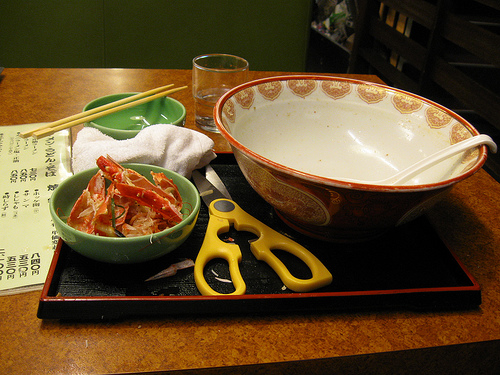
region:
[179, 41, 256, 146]
Small clear glass with water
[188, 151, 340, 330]
Scissors with yellow handles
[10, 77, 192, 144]
Two brown chopsticks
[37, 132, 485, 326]
Black and red food tray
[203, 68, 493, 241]
Large red white and brown bowl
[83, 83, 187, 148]
Small green bowl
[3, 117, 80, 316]
Black and white chinese menu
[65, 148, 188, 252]
Red crab meat in bowl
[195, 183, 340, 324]
Yellow handle on shears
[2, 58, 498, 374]
Pretty brown table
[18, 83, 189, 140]
Two chopsticks laying across a green bowl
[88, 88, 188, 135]
Small green bowl with chopsticks laying on top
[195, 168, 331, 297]
Pair of scissors with a yellow handle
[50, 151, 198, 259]
Medium green bowl with crustacean remains inside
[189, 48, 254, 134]
Small glass half-filled with water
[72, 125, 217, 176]
Small wadded up white towel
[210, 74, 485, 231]
Large empty bowl with decorative trim on the brim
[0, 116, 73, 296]
A light green laminated menu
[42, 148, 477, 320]
A black tray with a red brim full of dinner contents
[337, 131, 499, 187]
A white plastic spoon sitting in a large bowl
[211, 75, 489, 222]
ceramic Asian style soup bowl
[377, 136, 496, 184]
ceramic soup spoon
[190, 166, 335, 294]
kitchen scissors with yellow handles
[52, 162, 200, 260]
empty shrimp shells in green ceramic bowl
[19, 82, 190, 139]
pair of wooden chopsticks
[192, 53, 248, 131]
clear water glass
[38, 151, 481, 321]
laquered serving tray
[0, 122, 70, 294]
ethnic restaurant menu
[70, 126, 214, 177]
white cloth napkin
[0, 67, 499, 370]
three bowls, a menu and a glass on tabletopo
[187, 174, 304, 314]
yellow scissors on tray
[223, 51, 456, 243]
white bowl on black tray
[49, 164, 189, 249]
small green bowl on tray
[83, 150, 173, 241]
pieces of meat in green bowl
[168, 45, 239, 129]
glass of water on table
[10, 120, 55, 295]
white menu on left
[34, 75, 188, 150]
chop sticks on top of bowl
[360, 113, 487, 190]
white spoon in bowl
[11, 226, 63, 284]
black writing on white menu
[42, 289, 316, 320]
red edge of black tray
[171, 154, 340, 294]
yellow pair of scissors on a plate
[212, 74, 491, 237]
an empty bowl with a spoon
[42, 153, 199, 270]
a side dish of meat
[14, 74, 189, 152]
a wooden chopstick lay on top of bowl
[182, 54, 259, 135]
a cup of water on table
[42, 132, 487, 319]
a medium size black plate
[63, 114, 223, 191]
a white hand towel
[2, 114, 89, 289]
a restaurant menu on table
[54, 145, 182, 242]
small slices of meat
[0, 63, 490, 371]
a table with a plate of cup and bowls